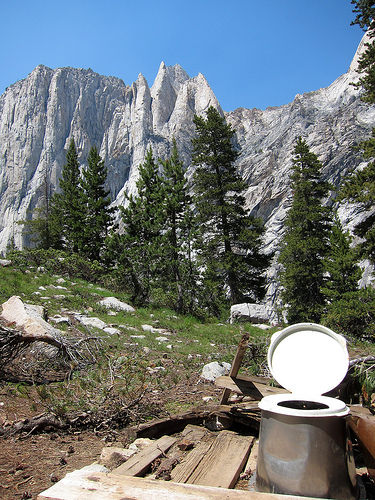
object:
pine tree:
[186, 100, 270, 332]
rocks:
[56, 284, 68, 292]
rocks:
[103, 327, 121, 335]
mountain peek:
[347, 17, 373, 75]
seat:
[258, 392, 350, 418]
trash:
[80, 348, 268, 499]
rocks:
[124, 338, 138, 349]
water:
[233, 469, 261, 489]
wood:
[234, 439, 272, 494]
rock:
[198, 360, 232, 383]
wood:
[124, 331, 291, 437]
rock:
[130, 334, 146, 340]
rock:
[150, 327, 167, 334]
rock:
[96, 296, 135, 315]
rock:
[80, 312, 120, 335]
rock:
[50, 314, 70, 324]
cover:
[248, 304, 347, 399]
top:
[50, 59, 164, 96]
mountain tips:
[124, 59, 215, 106]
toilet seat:
[254, 323, 351, 428]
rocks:
[11, 309, 68, 359]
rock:
[230, 301, 268, 321]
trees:
[188, 105, 276, 324]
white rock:
[32, 282, 49, 293]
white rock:
[1, 254, 12, 268]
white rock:
[54, 273, 67, 285]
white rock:
[40, 293, 53, 301]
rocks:
[166, 343, 174, 349]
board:
[35, 467, 321, 498]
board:
[109, 431, 178, 481]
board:
[172, 420, 255, 486]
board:
[239, 435, 266, 482]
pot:
[250, 317, 356, 498]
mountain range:
[1, 19, 373, 320]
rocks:
[39, 286, 48, 291]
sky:
[0, 0, 374, 110]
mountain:
[2, 36, 374, 315]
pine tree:
[267, 135, 340, 327]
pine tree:
[191, 108, 276, 308]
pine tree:
[156, 133, 192, 303]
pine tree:
[117, 141, 166, 304]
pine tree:
[52, 133, 90, 254]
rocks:
[173, 313, 178, 320]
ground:
[26, 268, 373, 480]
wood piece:
[220, 327, 252, 408]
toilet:
[257, 316, 352, 424]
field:
[59, 229, 317, 499]